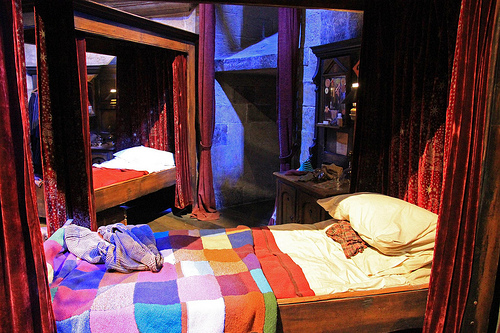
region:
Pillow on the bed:
[377, 211, 404, 233]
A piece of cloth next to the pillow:
[339, 223, 348, 235]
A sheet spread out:
[310, 256, 335, 273]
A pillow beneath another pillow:
[363, 254, 380, 268]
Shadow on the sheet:
[297, 224, 312, 228]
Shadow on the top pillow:
[326, 200, 334, 207]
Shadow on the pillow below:
[320, 222, 325, 227]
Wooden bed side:
[319, 316, 374, 328]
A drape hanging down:
[202, 159, 209, 184]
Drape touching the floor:
[201, 216, 214, 220]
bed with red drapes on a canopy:
[1, 3, 497, 328]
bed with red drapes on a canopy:
[54, 17, 200, 227]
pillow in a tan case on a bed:
[317, 191, 440, 259]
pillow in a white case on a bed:
[112, 143, 177, 174]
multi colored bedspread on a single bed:
[39, 218, 281, 328]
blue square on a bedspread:
[133, 301, 184, 331]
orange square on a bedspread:
[204, 246, 242, 262]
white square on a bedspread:
[184, 298, 224, 330]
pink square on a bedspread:
[48, 284, 95, 324]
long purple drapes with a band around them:
[269, 0, 303, 232]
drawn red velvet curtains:
[382, 2, 499, 332]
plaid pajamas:
[323, 218, 369, 261]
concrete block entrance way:
[211, 1, 356, 204]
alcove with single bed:
[28, 0, 196, 235]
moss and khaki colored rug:
[146, 211, 236, 241]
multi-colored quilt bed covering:
[41, 221, 280, 331]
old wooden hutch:
[270, 33, 360, 226]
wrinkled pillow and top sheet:
[271, 187, 440, 298]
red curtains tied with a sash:
[187, 1, 222, 223]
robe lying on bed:
[62, 219, 166, 274]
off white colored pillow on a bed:
[317, 187, 441, 255]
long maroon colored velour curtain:
[427, 2, 498, 327]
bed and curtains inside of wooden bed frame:
[48, 2, 200, 221]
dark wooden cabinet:
[308, 36, 363, 173]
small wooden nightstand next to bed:
[268, 162, 352, 225]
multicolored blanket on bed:
[30, 223, 277, 330]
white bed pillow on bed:
[110, 146, 175, 169]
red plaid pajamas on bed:
[321, 218, 371, 259]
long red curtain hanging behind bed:
[356, 6, 456, 193]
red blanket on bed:
[90, 167, 145, 190]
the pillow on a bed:
[311, 186, 415, 271]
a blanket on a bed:
[147, 174, 337, 321]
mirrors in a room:
[82, 23, 221, 208]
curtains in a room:
[155, 18, 270, 202]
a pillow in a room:
[315, 203, 405, 257]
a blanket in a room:
[160, 186, 310, 316]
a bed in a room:
[250, 175, 433, 326]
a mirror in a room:
[58, 50, 214, 197]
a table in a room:
[264, 146, 368, 210]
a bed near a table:
[194, 123, 385, 293]